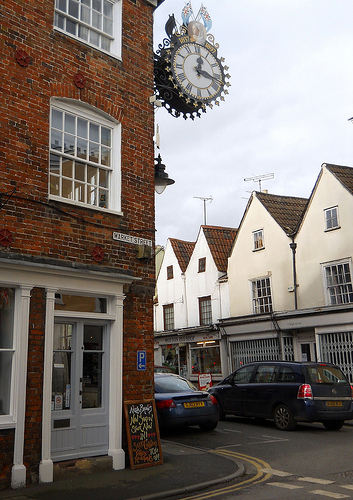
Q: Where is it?
A: This is at the shop.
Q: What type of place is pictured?
A: It is a shop.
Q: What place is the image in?
A: It is at the shop.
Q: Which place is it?
A: It is a shop.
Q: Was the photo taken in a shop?
A: Yes, it was taken in a shop.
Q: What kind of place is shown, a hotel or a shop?
A: It is a shop.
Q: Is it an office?
A: No, it is a shop.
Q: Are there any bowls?
A: No, there are no bowls.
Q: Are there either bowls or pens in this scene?
A: No, there are no bowls or pens.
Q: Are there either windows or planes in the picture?
A: Yes, there are windows.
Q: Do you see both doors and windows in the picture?
A: Yes, there are both windows and a door.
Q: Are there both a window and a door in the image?
A: Yes, there are both a window and a door.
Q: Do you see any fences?
A: No, there are no fences.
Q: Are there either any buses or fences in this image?
A: No, there are no fences or buses.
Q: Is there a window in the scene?
A: Yes, there are windows.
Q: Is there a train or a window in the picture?
A: Yes, there are windows.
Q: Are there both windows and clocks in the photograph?
A: Yes, there are both windows and a clock.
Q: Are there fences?
A: No, there are no fences.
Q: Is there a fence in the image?
A: No, there are no fences.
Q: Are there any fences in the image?
A: No, there are no fences.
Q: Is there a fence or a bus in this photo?
A: No, there are no fences or buses.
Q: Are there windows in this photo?
A: Yes, there are windows.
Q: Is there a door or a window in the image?
A: Yes, there are windows.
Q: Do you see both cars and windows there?
A: Yes, there are both windows and a car.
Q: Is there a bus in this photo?
A: No, there are no buses.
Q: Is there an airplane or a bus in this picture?
A: No, there are no buses or airplanes.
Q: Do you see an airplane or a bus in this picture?
A: No, there are no buses or airplanes.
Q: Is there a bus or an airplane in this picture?
A: No, there are no buses or airplanes.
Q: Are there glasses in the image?
A: No, there are no glasses.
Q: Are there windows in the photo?
A: Yes, there are windows.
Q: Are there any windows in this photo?
A: Yes, there are windows.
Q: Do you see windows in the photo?
A: Yes, there are windows.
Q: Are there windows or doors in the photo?
A: Yes, there are windows.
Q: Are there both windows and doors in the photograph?
A: Yes, there are both windows and a door.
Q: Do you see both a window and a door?
A: Yes, there are both a window and a door.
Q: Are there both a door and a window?
A: Yes, there are both a window and a door.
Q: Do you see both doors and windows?
A: Yes, there are both windows and a door.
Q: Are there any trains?
A: No, there are no trains.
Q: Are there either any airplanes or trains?
A: No, there are no trains or airplanes.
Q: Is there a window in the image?
A: Yes, there are windows.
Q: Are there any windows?
A: Yes, there are windows.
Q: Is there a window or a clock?
A: Yes, there are windows.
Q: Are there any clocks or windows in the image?
A: Yes, there are windows.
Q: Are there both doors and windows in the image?
A: Yes, there are both windows and a door.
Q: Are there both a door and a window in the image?
A: Yes, there are both a window and a door.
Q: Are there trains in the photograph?
A: No, there are no trains.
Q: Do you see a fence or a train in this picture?
A: No, there are no trains or fences.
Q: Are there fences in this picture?
A: No, there are no fences.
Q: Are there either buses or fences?
A: No, there are no fences or buses.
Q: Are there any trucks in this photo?
A: No, there are no trucks.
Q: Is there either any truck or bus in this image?
A: No, there are no trucks or buses.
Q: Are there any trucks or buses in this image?
A: No, there are no trucks or buses.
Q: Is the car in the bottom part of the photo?
A: Yes, the car is in the bottom of the image.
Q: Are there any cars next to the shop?
A: Yes, there is a car next to the shop.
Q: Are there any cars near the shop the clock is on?
A: Yes, there is a car near the shop.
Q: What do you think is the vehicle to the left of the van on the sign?
A: The vehicle is a car.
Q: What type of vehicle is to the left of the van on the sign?
A: The vehicle is a car.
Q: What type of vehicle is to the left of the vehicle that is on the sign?
A: The vehicle is a car.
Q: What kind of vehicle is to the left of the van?
A: The vehicle is a car.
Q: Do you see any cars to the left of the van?
A: Yes, there is a car to the left of the van.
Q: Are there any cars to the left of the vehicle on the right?
A: Yes, there is a car to the left of the van.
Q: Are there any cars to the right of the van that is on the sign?
A: No, the car is to the left of the van.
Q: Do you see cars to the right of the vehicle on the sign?
A: No, the car is to the left of the van.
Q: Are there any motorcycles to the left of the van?
A: No, there is a car to the left of the van.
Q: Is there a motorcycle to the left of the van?
A: No, there is a car to the left of the van.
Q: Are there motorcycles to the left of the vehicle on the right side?
A: No, there is a car to the left of the van.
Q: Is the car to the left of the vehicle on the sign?
A: Yes, the car is to the left of the van.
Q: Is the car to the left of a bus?
A: No, the car is to the left of the van.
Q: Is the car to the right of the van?
A: No, the car is to the left of the van.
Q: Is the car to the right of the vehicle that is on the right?
A: No, the car is to the left of the van.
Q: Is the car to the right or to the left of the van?
A: The car is to the left of the van.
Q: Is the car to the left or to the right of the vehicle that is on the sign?
A: The car is to the left of the van.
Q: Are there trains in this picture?
A: No, there are no trains.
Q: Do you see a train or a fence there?
A: No, there are no trains or fences.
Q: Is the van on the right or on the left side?
A: The van is on the right of the image.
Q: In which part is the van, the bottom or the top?
A: The van is in the bottom of the image.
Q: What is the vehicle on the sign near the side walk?
A: The vehicle is a van.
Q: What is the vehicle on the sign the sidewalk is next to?
A: The vehicle is a van.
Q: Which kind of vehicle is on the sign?
A: The vehicle is a van.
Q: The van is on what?
A: The van is on the sign.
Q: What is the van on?
A: The van is on the sign.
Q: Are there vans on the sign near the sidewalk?
A: Yes, there is a van on the sign.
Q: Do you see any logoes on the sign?
A: No, there is a van on the sign.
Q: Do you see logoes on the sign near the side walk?
A: No, there is a van on the sign.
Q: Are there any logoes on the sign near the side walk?
A: No, there is a van on the sign.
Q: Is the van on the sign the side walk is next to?
A: Yes, the van is on the sign.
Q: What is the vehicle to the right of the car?
A: The vehicle is a van.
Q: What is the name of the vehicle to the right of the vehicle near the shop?
A: The vehicle is a van.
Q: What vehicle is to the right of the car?
A: The vehicle is a van.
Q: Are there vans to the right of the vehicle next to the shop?
A: Yes, there is a van to the right of the car.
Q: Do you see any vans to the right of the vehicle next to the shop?
A: Yes, there is a van to the right of the car.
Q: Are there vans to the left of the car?
A: No, the van is to the right of the car.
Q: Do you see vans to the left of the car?
A: No, the van is to the right of the car.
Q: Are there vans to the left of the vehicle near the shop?
A: No, the van is to the right of the car.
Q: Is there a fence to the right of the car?
A: No, there is a van to the right of the car.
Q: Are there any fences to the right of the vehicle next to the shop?
A: No, there is a van to the right of the car.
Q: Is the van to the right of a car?
A: Yes, the van is to the right of a car.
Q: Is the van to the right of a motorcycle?
A: No, the van is to the right of a car.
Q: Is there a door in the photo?
A: Yes, there is a door.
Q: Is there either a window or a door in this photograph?
A: Yes, there is a door.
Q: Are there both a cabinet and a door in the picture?
A: No, there is a door but no cabinets.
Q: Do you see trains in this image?
A: No, there are no trains.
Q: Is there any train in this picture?
A: No, there are no trains.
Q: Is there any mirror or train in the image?
A: No, there are no trains or mirrors.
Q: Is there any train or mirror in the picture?
A: No, there are no trains or mirrors.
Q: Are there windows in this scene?
A: Yes, there are windows.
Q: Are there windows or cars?
A: Yes, there are windows.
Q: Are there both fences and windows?
A: No, there are windows but no fences.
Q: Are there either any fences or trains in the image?
A: No, there are no fences or trains.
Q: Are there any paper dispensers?
A: No, there are no paper dispensers.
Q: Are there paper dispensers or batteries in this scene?
A: No, there are no paper dispensers or batteries.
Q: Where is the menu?
A: The menu is on the shop.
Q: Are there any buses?
A: No, there are no buses.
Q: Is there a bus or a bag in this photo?
A: No, there are no buses or bags.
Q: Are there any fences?
A: No, there are no fences.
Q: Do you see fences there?
A: No, there are no fences.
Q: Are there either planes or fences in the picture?
A: No, there are no fences or planes.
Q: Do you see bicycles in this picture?
A: No, there are no bicycles.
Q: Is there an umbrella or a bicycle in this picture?
A: No, there are no bicycles or umbrellas.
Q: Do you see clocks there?
A: Yes, there is a clock.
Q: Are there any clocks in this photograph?
A: Yes, there is a clock.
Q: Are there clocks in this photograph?
A: Yes, there is a clock.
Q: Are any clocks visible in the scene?
A: Yes, there is a clock.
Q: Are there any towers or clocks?
A: Yes, there is a clock.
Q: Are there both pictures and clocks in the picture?
A: No, there is a clock but no pictures.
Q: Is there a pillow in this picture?
A: No, there are no pillows.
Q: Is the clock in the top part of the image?
A: Yes, the clock is in the top of the image.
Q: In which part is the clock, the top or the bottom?
A: The clock is in the top of the image.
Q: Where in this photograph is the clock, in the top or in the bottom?
A: The clock is in the top of the image.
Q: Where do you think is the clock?
A: The clock is on the shop.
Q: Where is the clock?
A: The clock is on the shop.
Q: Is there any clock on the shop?
A: Yes, there is a clock on the shop.